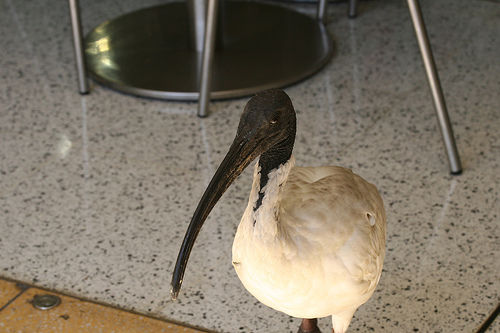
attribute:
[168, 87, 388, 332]
bird — white, black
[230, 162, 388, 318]
body — white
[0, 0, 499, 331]
floor — tiled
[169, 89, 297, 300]
head — black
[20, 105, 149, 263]
floor — white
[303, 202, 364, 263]
feathers — white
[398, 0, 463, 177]
leg — silver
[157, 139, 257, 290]
beak — long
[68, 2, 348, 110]
base — silver, round